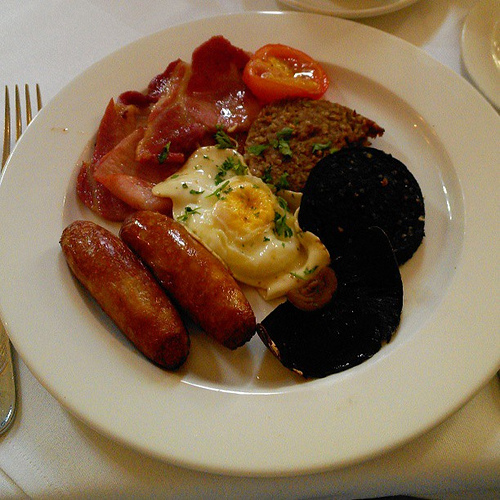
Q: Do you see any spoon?
A: No, there are no spoons.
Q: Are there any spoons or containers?
A: No, there are no spoons or containers.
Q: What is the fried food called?
A: The food is an egg.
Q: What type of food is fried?
A: The food is an egg.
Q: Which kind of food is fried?
A: The food is an egg.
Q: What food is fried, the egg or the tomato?
A: The egg is fried.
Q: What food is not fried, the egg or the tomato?
A: The tomato is not fried.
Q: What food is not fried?
A: The food is a tomato.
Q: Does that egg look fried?
A: Yes, the egg is fried.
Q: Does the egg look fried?
A: Yes, the egg is fried.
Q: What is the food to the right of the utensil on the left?
A: The food is an egg.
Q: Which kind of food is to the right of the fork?
A: The food is an egg.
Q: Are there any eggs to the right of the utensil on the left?
A: Yes, there is an egg to the right of the fork.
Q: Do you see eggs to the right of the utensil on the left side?
A: Yes, there is an egg to the right of the fork.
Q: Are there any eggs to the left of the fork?
A: No, the egg is to the right of the fork.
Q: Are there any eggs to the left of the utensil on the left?
A: No, the egg is to the right of the fork.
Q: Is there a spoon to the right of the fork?
A: No, there is an egg to the right of the fork.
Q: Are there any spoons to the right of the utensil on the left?
A: No, there is an egg to the right of the fork.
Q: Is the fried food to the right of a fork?
A: Yes, the egg is to the right of a fork.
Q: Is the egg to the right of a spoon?
A: No, the egg is to the right of a fork.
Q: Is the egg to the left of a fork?
A: No, the egg is to the right of a fork.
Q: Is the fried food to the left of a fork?
A: No, the egg is to the right of a fork.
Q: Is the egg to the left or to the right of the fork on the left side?
A: The egg is to the right of the fork.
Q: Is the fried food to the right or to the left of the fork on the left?
A: The egg is to the right of the fork.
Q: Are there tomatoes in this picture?
A: Yes, there is a tomato.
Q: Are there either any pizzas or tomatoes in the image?
A: Yes, there is a tomato.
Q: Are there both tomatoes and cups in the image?
A: No, there is a tomato but no cups.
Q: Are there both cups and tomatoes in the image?
A: No, there is a tomato but no cups.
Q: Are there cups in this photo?
A: No, there are no cups.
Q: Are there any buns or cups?
A: No, there are no cups or buns.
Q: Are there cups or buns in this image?
A: No, there are no cups or buns.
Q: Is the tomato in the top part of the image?
A: Yes, the tomato is in the top of the image.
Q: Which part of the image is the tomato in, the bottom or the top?
A: The tomato is in the top of the image.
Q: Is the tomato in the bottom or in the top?
A: The tomato is in the top of the image.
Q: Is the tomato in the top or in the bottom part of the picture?
A: The tomato is in the top of the image.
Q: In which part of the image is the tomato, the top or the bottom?
A: The tomato is in the top of the image.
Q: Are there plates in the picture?
A: Yes, there is a plate.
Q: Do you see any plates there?
A: Yes, there is a plate.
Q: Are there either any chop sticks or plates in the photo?
A: Yes, there is a plate.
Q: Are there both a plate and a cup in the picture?
A: No, there is a plate but no cups.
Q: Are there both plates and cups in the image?
A: No, there is a plate but no cups.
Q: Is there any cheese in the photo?
A: No, there is no cheese.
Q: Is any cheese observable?
A: No, there is no cheese.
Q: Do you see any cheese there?
A: No, there is no cheese.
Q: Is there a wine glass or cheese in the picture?
A: No, there are no cheese or wine glasses.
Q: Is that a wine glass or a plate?
A: That is a plate.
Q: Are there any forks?
A: Yes, there is a fork.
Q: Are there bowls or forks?
A: Yes, there is a fork.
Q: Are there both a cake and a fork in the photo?
A: No, there is a fork but no cakes.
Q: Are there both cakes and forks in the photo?
A: No, there is a fork but no cakes.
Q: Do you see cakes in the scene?
A: No, there are no cakes.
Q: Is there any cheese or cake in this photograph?
A: No, there are no cakes or cheese.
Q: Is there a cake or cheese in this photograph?
A: No, there are no cakes or cheese.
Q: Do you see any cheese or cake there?
A: No, there are no cakes or cheese.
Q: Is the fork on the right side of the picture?
A: No, the fork is on the left of the image.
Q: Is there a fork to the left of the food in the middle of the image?
A: Yes, there is a fork to the left of the egg.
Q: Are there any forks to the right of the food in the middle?
A: No, the fork is to the left of the egg.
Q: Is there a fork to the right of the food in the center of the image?
A: No, the fork is to the left of the egg.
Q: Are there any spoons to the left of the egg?
A: No, there is a fork to the left of the egg.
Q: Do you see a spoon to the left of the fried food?
A: No, there is a fork to the left of the egg.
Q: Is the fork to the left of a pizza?
A: No, the fork is to the left of an egg.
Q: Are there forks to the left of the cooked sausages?
A: Yes, there is a fork to the left of the sausages.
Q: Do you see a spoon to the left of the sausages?
A: No, there is a fork to the left of the sausages.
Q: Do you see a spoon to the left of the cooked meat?
A: No, there is a fork to the left of the sausages.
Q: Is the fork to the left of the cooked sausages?
A: Yes, the fork is to the left of the sausages.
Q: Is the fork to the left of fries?
A: No, the fork is to the left of the sausages.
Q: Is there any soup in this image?
A: No, there is no soup.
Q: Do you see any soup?
A: No, there is no soup.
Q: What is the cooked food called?
A: The food is sausages.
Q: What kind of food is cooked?
A: The food is sausages.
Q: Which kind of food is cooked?
A: The food is sausages.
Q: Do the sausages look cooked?
A: Yes, the sausages are cooked.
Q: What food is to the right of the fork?
A: The food is sausages.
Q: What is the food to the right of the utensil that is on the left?
A: The food is sausages.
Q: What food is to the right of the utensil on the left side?
A: The food is sausages.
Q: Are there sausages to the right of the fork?
A: Yes, there are sausages to the right of the fork.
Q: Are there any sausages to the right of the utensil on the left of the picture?
A: Yes, there are sausages to the right of the fork.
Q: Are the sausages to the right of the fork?
A: Yes, the sausages are to the right of the fork.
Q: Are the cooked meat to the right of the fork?
A: Yes, the sausages are to the right of the fork.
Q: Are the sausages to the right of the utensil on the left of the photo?
A: Yes, the sausages are to the right of the fork.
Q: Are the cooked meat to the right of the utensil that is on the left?
A: Yes, the sausages are to the right of the fork.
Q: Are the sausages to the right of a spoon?
A: No, the sausages are to the right of the fork.